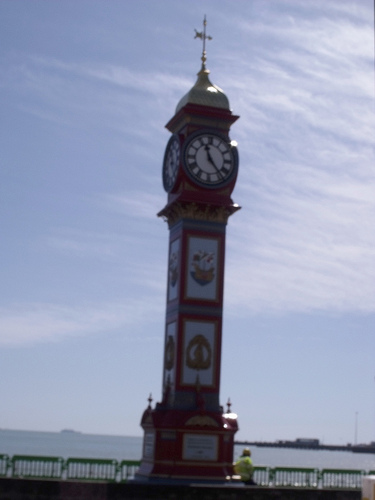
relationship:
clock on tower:
[160, 133, 188, 195] [148, 9, 233, 475]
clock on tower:
[184, 125, 240, 188] [148, 9, 233, 475]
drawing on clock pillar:
[187, 244, 219, 287] [184, 244, 218, 292]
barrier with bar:
[253, 467, 364, 488] [289, 469, 299, 485]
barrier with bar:
[0, 452, 141, 484] [289, 469, 299, 485]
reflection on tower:
[184, 474, 259, 491] [131, 13, 239, 484]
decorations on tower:
[182, 239, 223, 384] [112, 14, 303, 430]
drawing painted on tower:
[185, 236, 218, 301] [131, 13, 239, 484]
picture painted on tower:
[165, 239, 181, 298] [131, 13, 239, 484]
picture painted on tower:
[180, 321, 214, 384] [131, 13, 239, 484]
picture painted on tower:
[161, 321, 178, 382] [131, 13, 239, 484]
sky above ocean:
[2, 1, 132, 423] [1, 425, 354, 480]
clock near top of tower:
[156, 126, 235, 201] [139, 24, 266, 477]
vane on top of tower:
[192, 17, 218, 59] [131, 13, 239, 484]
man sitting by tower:
[233, 447, 257, 483] [146, 14, 257, 475]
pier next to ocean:
[3, 453, 374, 498] [4, 427, 370, 468]